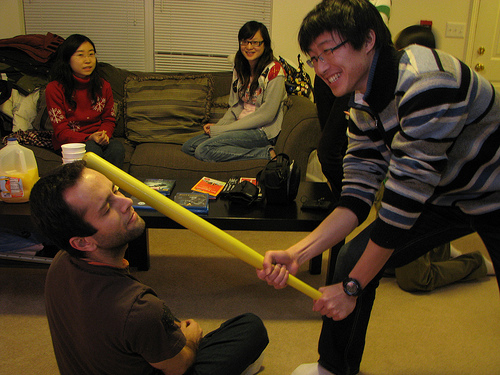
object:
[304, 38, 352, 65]
glasses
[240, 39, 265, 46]
glasses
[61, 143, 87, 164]
cups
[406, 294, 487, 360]
ground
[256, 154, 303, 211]
bag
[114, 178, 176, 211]
books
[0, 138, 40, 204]
juice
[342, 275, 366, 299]
watch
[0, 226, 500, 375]
carpet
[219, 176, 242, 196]
controller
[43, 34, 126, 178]
woman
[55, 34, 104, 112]
hair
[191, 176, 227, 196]
manual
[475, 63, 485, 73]
knobs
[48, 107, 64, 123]
snowflake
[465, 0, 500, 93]
door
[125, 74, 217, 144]
brown pillow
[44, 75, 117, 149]
sweater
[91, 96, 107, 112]
snowflakes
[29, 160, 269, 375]
man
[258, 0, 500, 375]
man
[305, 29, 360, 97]
face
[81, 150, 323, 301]
bat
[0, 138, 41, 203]
carton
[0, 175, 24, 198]
orange juice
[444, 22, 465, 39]
light switch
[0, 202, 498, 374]
floor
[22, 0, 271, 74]
blinds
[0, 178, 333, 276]
coffee table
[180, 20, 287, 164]
woman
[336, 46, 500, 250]
shirt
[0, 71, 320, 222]
couch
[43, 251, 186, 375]
shirt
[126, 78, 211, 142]
stripes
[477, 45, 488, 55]
lock